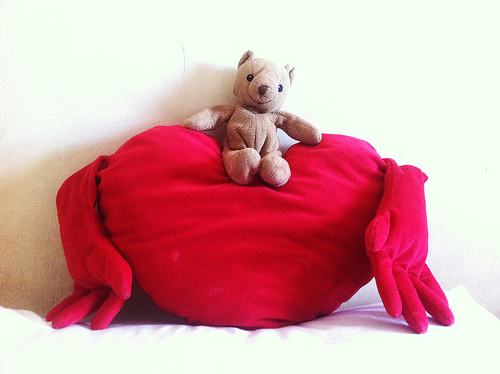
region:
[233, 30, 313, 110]
the head of a bear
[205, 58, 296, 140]
the brown head of a bear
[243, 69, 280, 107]
the nose of a bear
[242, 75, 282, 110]
the brown nose of a bear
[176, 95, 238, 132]
the arm of a bear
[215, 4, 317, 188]
the body of a bear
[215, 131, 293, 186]
the leg of a bear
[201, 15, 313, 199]
the brown body of a bear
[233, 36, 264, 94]
the ear of a bear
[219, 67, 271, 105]
the black eye of a bear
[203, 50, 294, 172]
a teddy bear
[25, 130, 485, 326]
a red heart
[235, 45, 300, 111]
the face of the teddy bear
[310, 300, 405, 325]
the shadow on the bed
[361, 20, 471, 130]
the white wall behind the bear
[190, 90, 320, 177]
the body of the teddy bear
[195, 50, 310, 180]
a stuffed bear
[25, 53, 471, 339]
these are teddy bears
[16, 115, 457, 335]
this is a teddy bear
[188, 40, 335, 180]
this is a teddy bear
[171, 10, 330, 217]
This is a tedbear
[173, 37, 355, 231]
This is a tedbear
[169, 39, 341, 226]
This is a tedbear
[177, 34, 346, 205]
This is a tedbear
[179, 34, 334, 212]
This is a tedbear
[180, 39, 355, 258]
This is a tedbear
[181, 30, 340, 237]
This is a tedbear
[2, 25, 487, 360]
A stuffed animal on a cushion.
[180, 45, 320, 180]
The stuffed animal is a teddy bear.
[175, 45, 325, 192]
The teddy bear is light brown colored.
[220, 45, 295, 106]
The teddy bear has a smiling face.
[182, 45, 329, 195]
The bear is sitting on a cushion.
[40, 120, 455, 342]
The cushion is red.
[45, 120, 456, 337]
The red cushion is heart shaped.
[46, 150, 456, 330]
The heart shaped cushion has two hands.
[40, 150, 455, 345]
The hands are on each side of the cushion.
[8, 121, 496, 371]
The cushion is on a white bed.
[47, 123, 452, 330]
A stuffed red heart with hands.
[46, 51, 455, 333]
A small bear sitting on a heart.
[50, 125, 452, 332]
A red plush with a small stain.